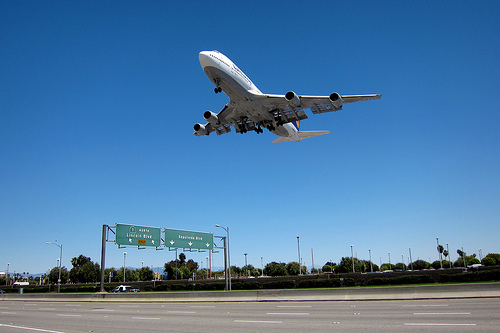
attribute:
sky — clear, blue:
[0, 1, 497, 273]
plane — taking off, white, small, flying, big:
[193, 46, 381, 145]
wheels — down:
[238, 116, 286, 133]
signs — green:
[115, 222, 214, 252]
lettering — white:
[124, 225, 205, 243]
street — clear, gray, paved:
[2, 287, 498, 331]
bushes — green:
[51, 253, 499, 284]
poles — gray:
[98, 223, 228, 293]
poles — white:
[296, 235, 413, 275]